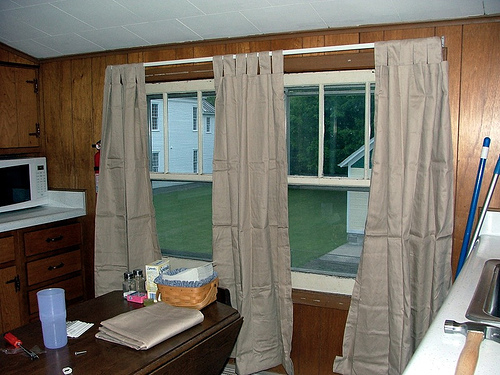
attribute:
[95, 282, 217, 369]
hoodie — red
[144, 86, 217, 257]
window — open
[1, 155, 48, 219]
microwave — white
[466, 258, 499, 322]
sink — kitchen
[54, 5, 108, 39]
tile — white